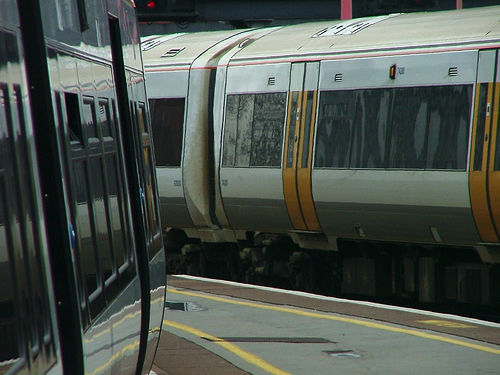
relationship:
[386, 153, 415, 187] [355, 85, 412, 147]
part of a glass window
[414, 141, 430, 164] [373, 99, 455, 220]
part of a glass window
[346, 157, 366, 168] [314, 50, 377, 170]
part of a glass window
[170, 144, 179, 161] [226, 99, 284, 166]
part of a glass window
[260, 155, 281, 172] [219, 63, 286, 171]
part of a glass window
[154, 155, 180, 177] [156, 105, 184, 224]
part of a glass window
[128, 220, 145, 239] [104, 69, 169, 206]
part of a glass window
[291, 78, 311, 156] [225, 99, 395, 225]
yellow door on train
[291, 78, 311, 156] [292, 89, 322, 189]
yellow door on train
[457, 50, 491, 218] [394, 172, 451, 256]
yellow door on train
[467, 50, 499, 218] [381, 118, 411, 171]
yellow door on train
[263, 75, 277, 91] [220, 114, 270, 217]
small vent on train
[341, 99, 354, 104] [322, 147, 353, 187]
small vent on train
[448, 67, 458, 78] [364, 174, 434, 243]
small vent on train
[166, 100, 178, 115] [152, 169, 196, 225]
small vent on train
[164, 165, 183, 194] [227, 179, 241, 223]
small vent on train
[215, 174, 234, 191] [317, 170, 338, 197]
small vent on train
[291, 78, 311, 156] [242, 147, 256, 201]
yellow door on  train car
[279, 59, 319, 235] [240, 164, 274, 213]
door on  train car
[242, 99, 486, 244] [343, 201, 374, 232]
2 sets of doors on train car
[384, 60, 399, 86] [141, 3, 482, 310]
light on train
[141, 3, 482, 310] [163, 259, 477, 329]
train on track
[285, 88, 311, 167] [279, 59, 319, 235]
window on door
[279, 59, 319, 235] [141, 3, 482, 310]
door on train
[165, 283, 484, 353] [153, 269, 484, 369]
line on walkway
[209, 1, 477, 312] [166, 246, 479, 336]
car on tracks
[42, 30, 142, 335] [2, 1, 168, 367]
windows on train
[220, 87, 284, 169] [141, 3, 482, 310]
window on train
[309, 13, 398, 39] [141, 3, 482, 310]
mark on train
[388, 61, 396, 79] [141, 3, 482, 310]
light on train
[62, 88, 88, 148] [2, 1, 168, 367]
window on train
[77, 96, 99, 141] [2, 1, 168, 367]
window on train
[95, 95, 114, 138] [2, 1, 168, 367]
window on train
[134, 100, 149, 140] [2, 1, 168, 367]
window on train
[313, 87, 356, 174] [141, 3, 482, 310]
window on train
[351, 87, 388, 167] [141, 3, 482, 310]
window on train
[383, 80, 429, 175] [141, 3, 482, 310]
window on train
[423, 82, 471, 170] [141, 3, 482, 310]
window on train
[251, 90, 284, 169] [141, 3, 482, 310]
window on train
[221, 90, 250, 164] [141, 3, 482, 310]
window on train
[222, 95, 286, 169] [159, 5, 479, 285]
window on train